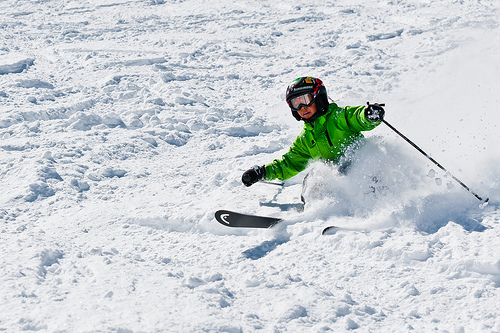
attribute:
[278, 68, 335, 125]
helmet — black, red, green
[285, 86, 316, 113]
goggles — black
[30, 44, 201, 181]
snow — messy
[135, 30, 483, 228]
skier — coming down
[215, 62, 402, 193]
jacket — green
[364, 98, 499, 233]
pole — black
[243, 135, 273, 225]
winter gloves — black, padded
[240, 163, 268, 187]
glove — black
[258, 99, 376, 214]
jacket — green, padded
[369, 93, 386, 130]
glove — black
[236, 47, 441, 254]
person — skiing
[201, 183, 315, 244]
ski — black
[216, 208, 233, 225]
symbol — white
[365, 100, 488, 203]
pole — black